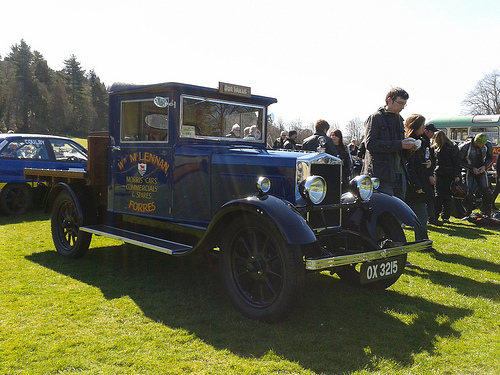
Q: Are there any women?
A: Yes, there is a woman.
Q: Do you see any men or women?
A: Yes, there is a woman.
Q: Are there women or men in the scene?
A: Yes, there is a woman.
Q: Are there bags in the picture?
A: No, there are no bags.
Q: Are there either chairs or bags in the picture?
A: No, there are no bags or chairs.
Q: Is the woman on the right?
A: Yes, the woman is on the right of the image.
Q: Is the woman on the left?
A: No, the woman is on the right of the image.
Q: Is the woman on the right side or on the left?
A: The woman is on the right of the image.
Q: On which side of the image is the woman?
A: The woman is on the right of the image.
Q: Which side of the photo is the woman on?
A: The woman is on the right of the image.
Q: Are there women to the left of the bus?
A: Yes, there is a woman to the left of the bus.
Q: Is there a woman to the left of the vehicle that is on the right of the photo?
A: Yes, there is a woman to the left of the bus.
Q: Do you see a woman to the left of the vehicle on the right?
A: Yes, there is a woman to the left of the bus.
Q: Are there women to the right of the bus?
A: No, the woman is to the left of the bus.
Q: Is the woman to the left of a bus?
A: Yes, the woman is to the left of a bus.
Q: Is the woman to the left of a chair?
A: No, the woman is to the left of a bus.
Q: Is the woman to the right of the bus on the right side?
A: No, the woman is to the left of the bus.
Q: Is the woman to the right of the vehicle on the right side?
A: No, the woman is to the left of the bus.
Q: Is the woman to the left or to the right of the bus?
A: The woman is to the left of the bus.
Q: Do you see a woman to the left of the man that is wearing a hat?
A: Yes, there is a woman to the left of the man.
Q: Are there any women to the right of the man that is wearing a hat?
A: No, the woman is to the left of the man.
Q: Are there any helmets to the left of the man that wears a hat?
A: No, there is a woman to the left of the man.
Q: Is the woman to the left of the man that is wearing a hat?
A: Yes, the woman is to the left of the man.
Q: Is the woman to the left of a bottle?
A: No, the woman is to the left of the man.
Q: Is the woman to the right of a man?
A: No, the woman is to the left of a man.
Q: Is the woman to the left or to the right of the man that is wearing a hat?
A: The woman is to the left of the man.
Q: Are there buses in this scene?
A: Yes, there is a bus.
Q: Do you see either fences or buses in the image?
A: Yes, there is a bus.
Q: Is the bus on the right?
A: Yes, the bus is on the right of the image.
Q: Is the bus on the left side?
A: No, the bus is on the right of the image.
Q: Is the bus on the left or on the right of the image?
A: The bus is on the right of the image.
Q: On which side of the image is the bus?
A: The bus is on the right of the image.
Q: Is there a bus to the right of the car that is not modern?
A: Yes, there is a bus to the right of the car.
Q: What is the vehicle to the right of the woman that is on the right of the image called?
A: The vehicle is a bus.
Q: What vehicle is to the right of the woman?
A: The vehicle is a bus.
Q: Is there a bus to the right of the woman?
A: Yes, there is a bus to the right of the woman.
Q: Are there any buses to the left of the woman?
A: No, the bus is to the right of the woman.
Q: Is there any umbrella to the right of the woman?
A: No, there is a bus to the right of the woman.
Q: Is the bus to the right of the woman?
A: Yes, the bus is to the right of the woman.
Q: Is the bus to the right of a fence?
A: No, the bus is to the right of the woman.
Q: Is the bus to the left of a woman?
A: No, the bus is to the right of a woman.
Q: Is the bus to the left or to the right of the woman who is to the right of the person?
A: The bus is to the right of the woman.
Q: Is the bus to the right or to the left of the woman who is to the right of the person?
A: The bus is to the right of the woman.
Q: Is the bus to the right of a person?
A: Yes, the bus is to the right of a person.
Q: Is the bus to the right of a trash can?
A: No, the bus is to the right of a person.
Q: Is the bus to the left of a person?
A: No, the bus is to the right of a person.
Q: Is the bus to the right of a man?
A: Yes, the bus is to the right of a man.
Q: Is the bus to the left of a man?
A: No, the bus is to the right of a man.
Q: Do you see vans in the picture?
A: No, there are no vans.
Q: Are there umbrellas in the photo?
A: No, there are no umbrellas.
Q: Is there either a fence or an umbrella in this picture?
A: No, there are no umbrellas or fences.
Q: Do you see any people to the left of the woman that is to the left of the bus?
A: Yes, there are people to the left of the woman.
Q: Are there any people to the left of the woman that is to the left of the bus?
A: Yes, there are people to the left of the woman.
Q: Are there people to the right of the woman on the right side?
A: No, the people are to the left of the woman.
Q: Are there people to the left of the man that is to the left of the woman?
A: Yes, there are people to the left of the man.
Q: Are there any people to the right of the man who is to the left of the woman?
A: No, the people are to the left of the man.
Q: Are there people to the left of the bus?
A: Yes, there are people to the left of the bus.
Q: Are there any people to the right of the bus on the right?
A: No, the people are to the left of the bus.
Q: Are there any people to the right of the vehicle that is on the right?
A: No, the people are to the left of the bus.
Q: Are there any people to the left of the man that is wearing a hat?
A: Yes, there are people to the left of the man.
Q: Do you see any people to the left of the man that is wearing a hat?
A: Yes, there are people to the left of the man.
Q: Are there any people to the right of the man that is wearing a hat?
A: No, the people are to the left of the man.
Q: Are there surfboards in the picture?
A: No, there are no surfboards.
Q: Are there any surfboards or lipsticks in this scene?
A: No, there are no surfboards or lipsticks.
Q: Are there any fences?
A: No, there are no fences.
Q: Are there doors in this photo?
A: Yes, there is a door.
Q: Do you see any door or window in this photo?
A: Yes, there is a door.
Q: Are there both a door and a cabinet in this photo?
A: No, there is a door but no cabinets.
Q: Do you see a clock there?
A: No, there are no clocks.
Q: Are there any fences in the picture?
A: No, there are no fences.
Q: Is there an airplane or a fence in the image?
A: No, there are no fences or airplanes.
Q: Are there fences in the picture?
A: No, there are no fences.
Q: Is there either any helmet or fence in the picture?
A: No, there are no fences or helmets.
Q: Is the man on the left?
A: No, the man is on the right of the image.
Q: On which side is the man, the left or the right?
A: The man is on the right of the image.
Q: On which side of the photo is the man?
A: The man is on the right of the image.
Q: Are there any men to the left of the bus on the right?
A: Yes, there is a man to the left of the bus.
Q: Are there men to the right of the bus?
A: No, the man is to the left of the bus.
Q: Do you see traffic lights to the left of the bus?
A: No, there is a man to the left of the bus.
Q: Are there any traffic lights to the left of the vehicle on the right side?
A: No, there is a man to the left of the bus.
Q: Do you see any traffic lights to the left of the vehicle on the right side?
A: No, there is a man to the left of the bus.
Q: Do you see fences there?
A: No, there are no fences.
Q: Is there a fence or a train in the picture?
A: No, there are no fences or trains.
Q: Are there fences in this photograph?
A: No, there are no fences.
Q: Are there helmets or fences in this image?
A: No, there are no fences or helmets.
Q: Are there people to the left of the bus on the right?
A: Yes, there is a person to the left of the bus.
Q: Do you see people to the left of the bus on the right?
A: Yes, there is a person to the left of the bus.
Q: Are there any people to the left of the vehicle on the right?
A: Yes, there is a person to the left of the bus.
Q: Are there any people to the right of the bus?
A: No, the person is to the left of the bus.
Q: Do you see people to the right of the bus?
A: No, the person is to the left of the bus.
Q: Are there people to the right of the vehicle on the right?
A: No, the person is to the left of the bus.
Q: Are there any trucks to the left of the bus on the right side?
A: No, there is a person to the left of the bus.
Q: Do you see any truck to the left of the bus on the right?
A: No, there is a person to the left of the bus.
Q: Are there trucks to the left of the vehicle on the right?
A: No, there is a person to the left of the bus.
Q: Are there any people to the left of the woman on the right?
A: Yes, there is a person to the left of the woman.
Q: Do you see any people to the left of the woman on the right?
A: Yes, there is a person to the left of the woman.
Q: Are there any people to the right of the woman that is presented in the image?
A: No, the person is to the left of the woman.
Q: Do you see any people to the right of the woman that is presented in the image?
A: No, the person is to the left of the woman.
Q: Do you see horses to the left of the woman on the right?
A: No, there is a person to the left of the woman.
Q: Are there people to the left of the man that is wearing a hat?
A: Yes, there is a person to the left of the man.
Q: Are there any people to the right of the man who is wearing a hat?
A: No, the person is to the left of the man.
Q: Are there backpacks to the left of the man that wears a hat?
A: No, there is a person to the left of the man.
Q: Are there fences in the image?
A: No, there are no fences.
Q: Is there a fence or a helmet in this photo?
A: No, there are no fences or helmets.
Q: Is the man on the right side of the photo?
A: Yes, the man is on the right of the image.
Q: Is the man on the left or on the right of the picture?
A: The man is on the right of the image.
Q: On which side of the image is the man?
A: The man is on the right of the image.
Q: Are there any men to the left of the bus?
A: Yes, there is a man to the left of the bus.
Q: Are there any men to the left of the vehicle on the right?
A: Yes, there is a man to the left of the bus.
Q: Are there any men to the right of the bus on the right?
A: No, the man is to the left of the bus.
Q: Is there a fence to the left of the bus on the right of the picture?
A: No, there is a man to the left of the bus.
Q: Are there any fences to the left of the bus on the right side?
A: No, there is a man to the left of the bus.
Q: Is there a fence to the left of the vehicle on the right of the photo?
A: No, there is a man to the left of the bus.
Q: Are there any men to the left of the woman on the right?
A: Yes, there is a man to the left of the woman.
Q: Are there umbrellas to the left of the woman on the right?
A: No, there is a man to the left of the woman.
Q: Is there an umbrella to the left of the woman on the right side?
A: No, there is a man to the left of the woman.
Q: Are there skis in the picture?
A: No, there are no skis.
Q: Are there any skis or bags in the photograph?
A: No, there are no skis or bags.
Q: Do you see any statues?
A: No, there are no statues.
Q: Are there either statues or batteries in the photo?
A: No, there are no statues or batteries.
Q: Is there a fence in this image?
A: No, there are no fences.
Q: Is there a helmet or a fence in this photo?
A: No, there are no fences or helmets.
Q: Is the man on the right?
A: Yes, the man is on the right of the image.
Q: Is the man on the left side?
A: No, the man is on the right of the image.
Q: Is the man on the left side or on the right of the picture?
A: The man is on the right of the image.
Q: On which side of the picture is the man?
A: The man is on the right of the image.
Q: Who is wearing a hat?
A: The man is wearing a hat.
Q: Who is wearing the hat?
A: The man is wearing a hat.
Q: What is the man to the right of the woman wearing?
A: The man is wearing a hat.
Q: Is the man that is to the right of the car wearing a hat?
A: Yes, the man is wearing a hat.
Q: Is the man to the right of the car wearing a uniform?
A: No, the man is wearing a hat.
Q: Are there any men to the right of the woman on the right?
A: Yes, there is a man to the right of the woman.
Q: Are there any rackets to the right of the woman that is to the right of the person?
A: No, there is a man to the right of the woman.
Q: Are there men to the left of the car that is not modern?
A: No, the man is to the right of the car.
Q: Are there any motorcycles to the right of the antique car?
A: No, there is a man to the right of the car.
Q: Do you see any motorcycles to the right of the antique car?
A: No, there is a man to the right of the car.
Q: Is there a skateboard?
A: No, there are no skateboards.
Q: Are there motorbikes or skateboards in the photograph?
A: No, there are no skateboards or motorbikes.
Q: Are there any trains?
A: No, there are no trains.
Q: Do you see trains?
A: No, there are no trains.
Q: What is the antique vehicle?
A: The vehicle is a car.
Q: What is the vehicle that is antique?
A: The vehicle is a car.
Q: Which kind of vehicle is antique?
A: The vehicle is a car.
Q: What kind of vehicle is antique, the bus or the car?
A: The car is antique.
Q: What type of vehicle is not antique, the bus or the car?
A: The bus is not antique.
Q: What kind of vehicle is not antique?
A: The vehicle is a bus.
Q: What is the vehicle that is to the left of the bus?
A: The vehicle is a car.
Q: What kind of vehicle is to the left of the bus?
A: The vehicle is a car.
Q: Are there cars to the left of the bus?
A: Yes, there is a car to the left of the bus.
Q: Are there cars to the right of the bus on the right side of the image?
A: No, the car is to the left of the bus.